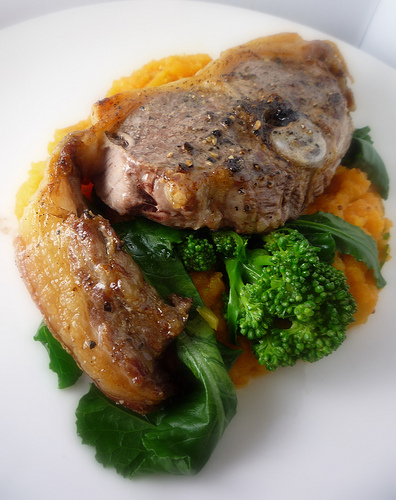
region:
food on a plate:
[38, 63, 352, 369]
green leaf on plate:
[151, 388, 236, 473]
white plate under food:
[305, 360, 366, 455]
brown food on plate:
[80, 268, 160, 359]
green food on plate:
[228, 231, 340, 351]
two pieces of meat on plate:
[32, 55, 313, 288]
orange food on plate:
[338, 175, 373, 213]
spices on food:
[154, 99, 280, 203]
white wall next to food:
[345, 5, 391, 42]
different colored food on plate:
[70, 84, 377, 330]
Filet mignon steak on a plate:
[105, 51, 352, 222]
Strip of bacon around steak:
[48, 143, 187, 406]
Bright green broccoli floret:
[229, 225, 350, 361]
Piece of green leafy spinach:
[65, 349, 251, 475]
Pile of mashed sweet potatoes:
[298, 162, 387, 317]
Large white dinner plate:
[1, 4, 391, 494]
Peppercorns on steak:
[191, 105, 246, 169]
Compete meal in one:
[12, 27, 375, 453]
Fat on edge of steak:
[92, 142, 176, 219]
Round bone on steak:
[262, 112, 328, 161]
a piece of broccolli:
[251, 231, 349, 361]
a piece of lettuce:
[89, 372, 230, 484]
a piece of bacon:
[68, 283, 165, 388]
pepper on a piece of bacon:
[68, 295, 134, 373]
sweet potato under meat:
[317, 178, 371, 281]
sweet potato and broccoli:
[228, 188, 378, 362]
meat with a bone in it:
[159, 42, 338, 220]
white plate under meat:
[0, 15, 187, 255]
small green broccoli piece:
[254, 295, 335, 358]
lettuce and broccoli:
[152, 293, 320, 438]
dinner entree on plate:
[1, 28, 377, 468]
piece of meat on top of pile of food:
[83, 20, 368, 235]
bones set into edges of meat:
[100, 75, 329, 178]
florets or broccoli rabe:
[160, 226, 367, 372]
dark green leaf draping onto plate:
[65, 221, 242, 474]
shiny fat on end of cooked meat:
[10, 125, 170, 412]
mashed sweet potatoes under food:
[122, 44, 386, 359]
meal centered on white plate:
[6, 0, 358, 480]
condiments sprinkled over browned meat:
[164, 95, 319, 172]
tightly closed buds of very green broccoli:
[174, 225, 240, 272]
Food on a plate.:
[33, 71, 393, 317]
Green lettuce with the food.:
[42, 369, 280, 496]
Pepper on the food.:
[72, 305, 225, 378]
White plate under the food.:
[202, 345, 371, 456]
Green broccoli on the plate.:
[228, 187, 370, 335]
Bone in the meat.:
[226, 79, 388, 211]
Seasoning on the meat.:
[164, 91, 334, 217]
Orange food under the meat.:
[218, 336, 258, 385]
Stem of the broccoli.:
[190, 216, 302, 346]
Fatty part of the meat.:
[29, 118, 253, 379]